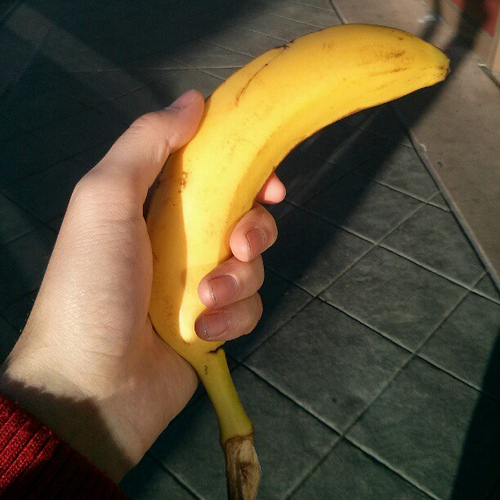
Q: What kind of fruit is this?
A: A banana.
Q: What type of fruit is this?
A: Banana.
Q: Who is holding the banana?
A: The student.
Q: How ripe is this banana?
A: Very ripe.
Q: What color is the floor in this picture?
A: Grey.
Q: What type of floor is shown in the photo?
A: Tile.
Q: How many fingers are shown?
A: Five.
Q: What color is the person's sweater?
A: Red.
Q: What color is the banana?
A: Yellow.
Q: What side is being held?
A: Top.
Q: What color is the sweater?
A: Red.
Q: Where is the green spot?
A: On the banana.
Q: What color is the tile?
A: Gray.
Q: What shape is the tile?
A: Diamond.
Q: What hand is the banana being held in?
A: Left.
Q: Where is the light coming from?
A: Behind.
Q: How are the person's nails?
A: Short.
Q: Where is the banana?
A: Person's hand.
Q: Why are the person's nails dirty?
A: Not cleaned.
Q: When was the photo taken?
A: Daylight.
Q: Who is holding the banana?
A: Person in red sweater.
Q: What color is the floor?
A: Grey.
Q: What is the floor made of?
A: Tiles.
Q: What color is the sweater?
A: Red.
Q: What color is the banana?
A: Yellow.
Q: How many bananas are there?
A: One.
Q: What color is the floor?
A: Black.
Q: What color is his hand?
A: White.